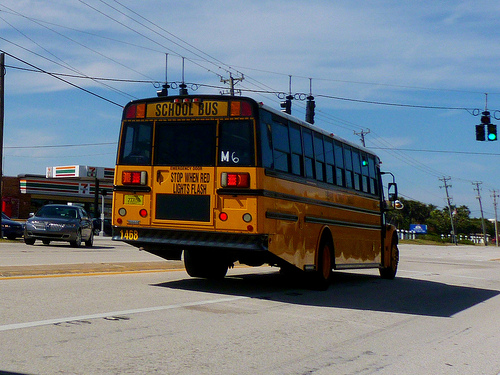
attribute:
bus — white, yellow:
[101, 93, 411, 288]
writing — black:
[168, 170, 211, 195]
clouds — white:
[0, 0, 497, 99]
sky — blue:
[0, 0, 497, 221]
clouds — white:
[2, 37, 201, 87]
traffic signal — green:
[451, 82, 493, 151]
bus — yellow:
[95, 103, 405, 292]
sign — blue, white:
[409, 214, 436, 240]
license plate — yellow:
[122, 192, 144, 206]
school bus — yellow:
[108, 92, 405, 293]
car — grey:
[19, 196, 103, 253]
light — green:
[484, 123, 497, 143]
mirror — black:
[369, 179, 416, 217]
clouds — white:
[115, 11, 449, 116]